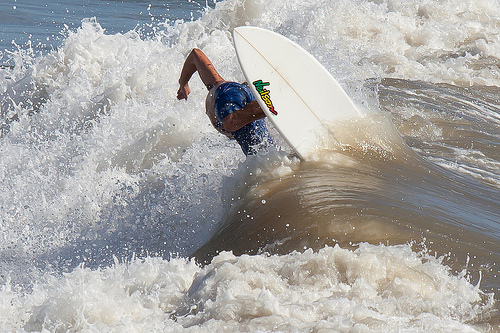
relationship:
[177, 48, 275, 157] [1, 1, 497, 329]
man surfing ocean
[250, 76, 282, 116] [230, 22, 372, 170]
writing on board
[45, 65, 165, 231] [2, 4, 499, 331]
waves in water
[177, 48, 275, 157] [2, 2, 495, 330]
man riding wave.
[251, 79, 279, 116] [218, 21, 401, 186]
writing on surfboard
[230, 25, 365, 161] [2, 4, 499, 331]
board splashing water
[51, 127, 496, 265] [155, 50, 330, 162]
water behind man